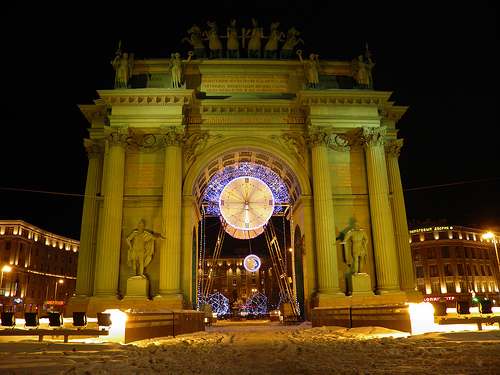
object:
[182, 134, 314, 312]
arch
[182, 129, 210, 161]
figure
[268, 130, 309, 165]
figure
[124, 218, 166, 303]
statue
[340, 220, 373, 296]
statue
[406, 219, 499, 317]
building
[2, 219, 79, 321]
building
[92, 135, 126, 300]
column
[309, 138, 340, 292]
column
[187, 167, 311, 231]
center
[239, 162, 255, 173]
lights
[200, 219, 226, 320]
lights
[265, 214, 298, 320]
lights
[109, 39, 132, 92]
statue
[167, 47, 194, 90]
statue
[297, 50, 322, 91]
statue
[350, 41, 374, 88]
statue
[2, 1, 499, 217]
sky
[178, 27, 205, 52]
horse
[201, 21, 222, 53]
horse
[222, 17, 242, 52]
horse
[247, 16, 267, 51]
horse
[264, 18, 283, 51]
horse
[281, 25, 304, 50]
horse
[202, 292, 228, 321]
tree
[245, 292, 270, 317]
tree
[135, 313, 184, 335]
wall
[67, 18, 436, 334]
building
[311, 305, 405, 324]
wall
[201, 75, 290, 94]
writing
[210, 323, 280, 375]
walkway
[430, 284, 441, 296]
window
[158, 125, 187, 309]
pedestal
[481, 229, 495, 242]
light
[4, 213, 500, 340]
background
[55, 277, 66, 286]
light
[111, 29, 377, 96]
top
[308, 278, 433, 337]
bottom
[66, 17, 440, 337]
monument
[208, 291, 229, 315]
lights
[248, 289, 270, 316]
lights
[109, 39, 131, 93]
goddess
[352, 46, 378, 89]
goddess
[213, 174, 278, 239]
clock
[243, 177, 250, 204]
hands